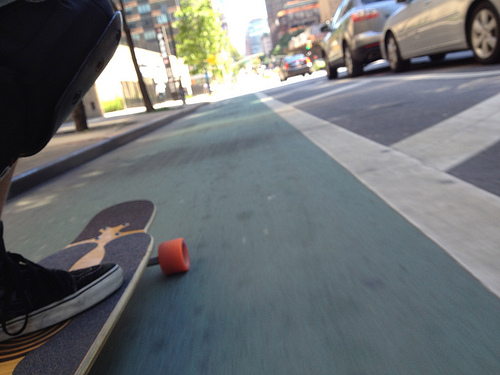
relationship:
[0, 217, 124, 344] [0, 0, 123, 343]
shoe on person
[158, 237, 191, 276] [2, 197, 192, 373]
wheel on skateboard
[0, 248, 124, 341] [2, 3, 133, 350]
shoe on person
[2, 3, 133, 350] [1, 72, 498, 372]
person on street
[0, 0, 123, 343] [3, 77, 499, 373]
person on road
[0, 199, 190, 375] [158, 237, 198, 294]
skateboard has wheels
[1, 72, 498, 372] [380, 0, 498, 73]
street has vehicular traffic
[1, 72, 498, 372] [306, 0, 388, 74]
street has vehicular traffic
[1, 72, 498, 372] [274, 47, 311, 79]
street has vehicular traffic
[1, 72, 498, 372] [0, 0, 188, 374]
street has vehicular traffic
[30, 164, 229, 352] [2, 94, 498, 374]
skateboard traveling on bike path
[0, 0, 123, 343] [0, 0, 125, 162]
person has pads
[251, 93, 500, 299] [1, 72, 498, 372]
lines on street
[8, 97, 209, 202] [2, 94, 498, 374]
curb on side of bike path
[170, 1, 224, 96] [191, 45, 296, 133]
tree on side of street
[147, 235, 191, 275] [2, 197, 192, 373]
wheel on skateboard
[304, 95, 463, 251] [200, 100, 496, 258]
lines in street